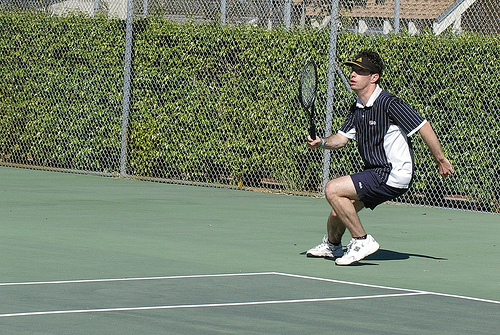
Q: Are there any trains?
A: No, there are no trains.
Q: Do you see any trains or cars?
A: No, there are no trains or cars.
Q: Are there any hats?
A: Yes, there is a hat.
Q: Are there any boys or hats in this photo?
A: Yes, there is a hat.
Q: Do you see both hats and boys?
A: No, there is a hat but no boys.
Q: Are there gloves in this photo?
A: No, there are no gloves.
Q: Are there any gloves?
A: No, there are no gloves.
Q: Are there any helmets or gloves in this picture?
A: No, there are no gloves or helmets.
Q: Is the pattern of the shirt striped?
A: Yes, the shirt is striped.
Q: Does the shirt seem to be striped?
A: Yes, the shirt is striped.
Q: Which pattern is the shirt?
A: The shirt is striped.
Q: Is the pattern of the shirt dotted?
A: No, the shirt is striped.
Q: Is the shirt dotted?
A: No, the shirt is striped.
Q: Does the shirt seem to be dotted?
A: No, the shirt is striped.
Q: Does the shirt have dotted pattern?
A: No, the shirt is striped.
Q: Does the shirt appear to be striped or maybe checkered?
A: The shirt is striped.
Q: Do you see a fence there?
A: Yes, there is a fence.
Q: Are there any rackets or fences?
A: Yes, there is a fence.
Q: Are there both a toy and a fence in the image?
A: No, there is a fence but no toys.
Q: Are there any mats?
A: No, there are no mats.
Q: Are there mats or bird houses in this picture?
A: No, there are no mats or bird houses.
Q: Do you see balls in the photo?
A: No, there are no balls.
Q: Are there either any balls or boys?
A: No, there are no balls or boys.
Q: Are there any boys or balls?
A: No, there are no balls or boys.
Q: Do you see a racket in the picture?
A: Yes, there is a racket.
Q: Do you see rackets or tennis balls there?
A: Yes, there is a racket.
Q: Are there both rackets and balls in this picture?
A: No, there is a racket but no balls.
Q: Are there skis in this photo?
A: No, there are no skis.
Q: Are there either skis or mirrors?
A: No, there are no skis or mirrors.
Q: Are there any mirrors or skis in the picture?
A: No, there are no skis or mirrors.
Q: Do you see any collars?
A: Yes, there is a collar.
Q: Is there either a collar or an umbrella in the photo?
A: Yes, there is a collar.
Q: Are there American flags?
A: No, there are no American flags.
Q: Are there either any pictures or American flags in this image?
A: No, there are no American flags or pictures.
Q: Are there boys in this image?
A: No, there are no boys.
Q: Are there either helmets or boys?
A: No, there are no boys or helmets.